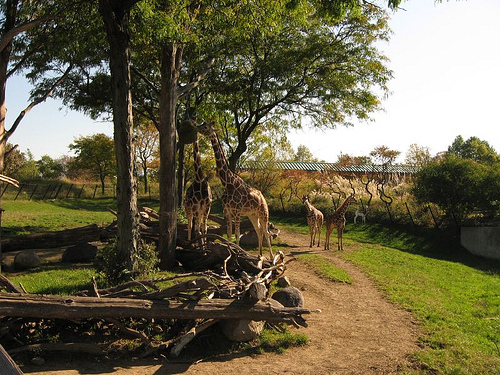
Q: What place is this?
A: It is a path.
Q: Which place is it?
A: It is a path.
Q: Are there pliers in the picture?
A: No, there are no pliers.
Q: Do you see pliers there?
A: No, there are no pliers.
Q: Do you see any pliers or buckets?
A: No, there are no pliers or buckets.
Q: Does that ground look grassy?
A: Yes, the ground is grassy.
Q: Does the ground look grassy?
A: Yes, the ground is grassy.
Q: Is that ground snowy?
A: No, the ground is grassy.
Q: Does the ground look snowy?
A: No, the ground is grassy.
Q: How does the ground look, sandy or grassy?
A: The ground is grassy.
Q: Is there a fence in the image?
A: Yes, there is a fence.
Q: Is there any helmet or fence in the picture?
A: Yes, there is a fence.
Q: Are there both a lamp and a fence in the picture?
A: No, there is a fence but no lamps.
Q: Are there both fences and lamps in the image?
A: No, there is a fence but no lamps.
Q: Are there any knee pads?
A: No, there are no knee pads.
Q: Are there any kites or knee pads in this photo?
A: No, there are no knee pads or kites.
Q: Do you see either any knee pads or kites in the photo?
A: No, there are no knee pads or kites.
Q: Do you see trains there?
A: No, there are no trains.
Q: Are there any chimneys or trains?
A: No, there are no trains or chimneys.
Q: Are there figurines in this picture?
A: No, there are no figurines.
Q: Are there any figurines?
A: No, there are no figurines.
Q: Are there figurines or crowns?
A: No, there are no figurines or crowns.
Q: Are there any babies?
A: Yes, there is a baby.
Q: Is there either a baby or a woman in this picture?
A: Yes, there is a baby.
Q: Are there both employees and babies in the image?
A: No, there is a baby but no employees.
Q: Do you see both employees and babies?
A: No, there is a baby but no employees.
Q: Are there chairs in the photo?
A: No, there are no chairs.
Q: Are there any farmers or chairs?
A: No, there are no chairs or farmers.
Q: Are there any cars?
A: No, there are no cars.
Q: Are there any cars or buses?
A: No, there are no cars or buses.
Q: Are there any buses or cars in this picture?
A: No, there are no cars or buses.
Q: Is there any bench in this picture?
A: No, there are no benches.